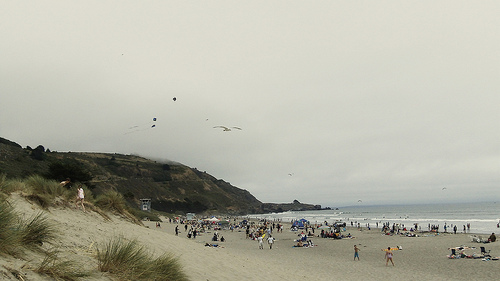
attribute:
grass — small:
[18, 180, 131, 210]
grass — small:
[34, 248, 91, 277]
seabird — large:
[213, 123, 243, 133]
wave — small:
[368, 211, 489, 224]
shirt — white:
[251, 227, 296, 267]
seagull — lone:
[210, 123, 244, 138]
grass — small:
[120, 240, 172, 278]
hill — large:
[0, 137, 330, 279]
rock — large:
[262, 198, 333, 210]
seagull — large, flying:
[186, 96, 254, 163]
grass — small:
[24, 172, 62, 198]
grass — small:
[22, 213, 58, 250]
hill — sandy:
[67, 200, 149, 241]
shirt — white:
[76, 185, 86, 201]